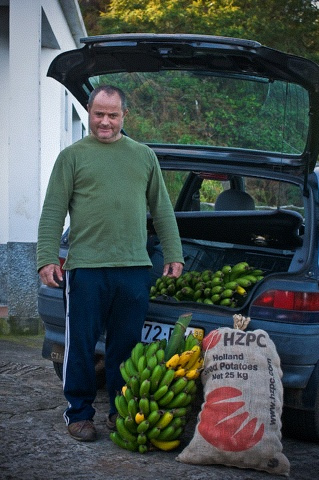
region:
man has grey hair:
[74, 80, 136, 146]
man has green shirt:
[55, 125, 183, 299]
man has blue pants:
[45, 257, 145, 441]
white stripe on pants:
[56, 265, 91, 398]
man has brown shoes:
[68, 404, 100, 444]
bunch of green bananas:
[101, 310, 207, 443]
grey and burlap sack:
[213, 307, 296, 466]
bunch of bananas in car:
[146, 263, 268, 288]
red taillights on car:
[252, 261, 316, 346]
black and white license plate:
[135, 312, 214, 360]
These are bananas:
[131, 350, 259, 466]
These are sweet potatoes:
[214, 344, 279, 429]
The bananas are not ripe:
[121, 402, 168, 431]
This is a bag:
[214, 324, 303, 456]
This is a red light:
[245, 266, 305, 321]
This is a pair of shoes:
[42, 418, 170, 448]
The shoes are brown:
[64, 408, 102, 436]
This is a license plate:
[146, 311, 199, 339]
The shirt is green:
[110, 214, 158, 262]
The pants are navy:
[35, 293, 132, 334]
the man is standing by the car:
[77, 79, 164, 242]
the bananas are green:
[136, 360, 158, 393]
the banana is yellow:
[169, 351, 190, 372]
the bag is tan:
[251, 381, 266, 409]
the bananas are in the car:
[190, 248, 235, 292]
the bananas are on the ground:
[118, 414, 160, 462]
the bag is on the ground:
[189, 443, 217, 474]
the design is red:
[208, 402, 240, 434]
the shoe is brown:
[68, 412, 98, 443]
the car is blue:
[277, 327, 310, 359]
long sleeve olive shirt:
[34, 134, 187, 267]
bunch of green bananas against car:
[110, 315, 205, 455]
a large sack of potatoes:
[178, 313, 289, 474]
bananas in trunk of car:
[150, 260, 266, 309]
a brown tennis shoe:
[67, 418, 98, 442]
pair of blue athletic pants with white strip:
[62, 265, 148, 429]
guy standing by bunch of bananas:
[39, 86, 185, 443]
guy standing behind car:
[36, 81, 185, 441]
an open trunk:
[44, 36, 317, 321]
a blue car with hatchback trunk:
[36, 29, 317, 443]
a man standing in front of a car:
[36, 83, 183, 440]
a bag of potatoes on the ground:
[177, 314, 291, 477]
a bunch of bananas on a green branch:
[111, 312, 202, 456]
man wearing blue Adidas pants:
[53, 269, 149, 423]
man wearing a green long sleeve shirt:
[37, 131, 183, 271]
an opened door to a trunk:
[45, 32, 316, 189]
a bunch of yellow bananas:
[164, 343, 201, 374]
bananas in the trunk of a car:
[149, 257, 263, 309]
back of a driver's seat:
[215, 188, 255, 211]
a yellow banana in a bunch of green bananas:
[235, 280, 246, 297]